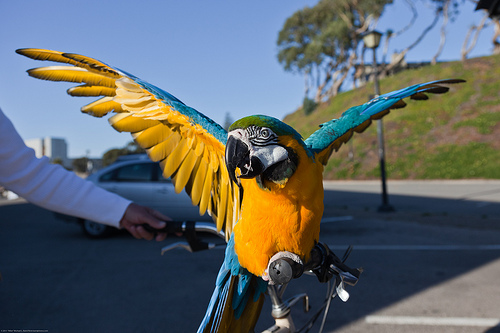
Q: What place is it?
A: It is a parking lot.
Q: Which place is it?
A: It is a parking lot.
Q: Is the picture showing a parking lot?
A: Yes, it is showing a parking lot.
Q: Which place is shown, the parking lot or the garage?
A: It is the parking lot.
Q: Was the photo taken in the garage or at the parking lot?
A: It was taken at the parking lot.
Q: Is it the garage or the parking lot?
A: It is the parking lot.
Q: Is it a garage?
A: No, it is a parking lot.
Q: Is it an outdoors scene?
A: Yes, it is outdoors.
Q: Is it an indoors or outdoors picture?
A: It is outdoors.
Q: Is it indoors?
A: No, it is outdoors.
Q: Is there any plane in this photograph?
A: No, there are no airplanes.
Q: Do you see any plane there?
A: No, there are no airplanes.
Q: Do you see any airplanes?
A: No, there are no airplanes.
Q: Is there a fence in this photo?
A: No, there are no fences.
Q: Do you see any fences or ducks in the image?
A: No, there are no fences or ducks.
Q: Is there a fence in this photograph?
A: No, there are no fences.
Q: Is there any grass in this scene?
A: Yes, there is grass.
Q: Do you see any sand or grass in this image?
A: Yes, there is grass.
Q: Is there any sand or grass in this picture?
A: Yes, there is grass.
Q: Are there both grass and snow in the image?
A: No, there is grass but no snow.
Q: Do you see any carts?
A: No, there are no carts.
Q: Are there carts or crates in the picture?
A: No, there are no carts or crates.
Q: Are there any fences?
A: No, there are no fences.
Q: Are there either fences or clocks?
A: No, there are no fences or clocks.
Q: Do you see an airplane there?
A: No, there are no airplanes.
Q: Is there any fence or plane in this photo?
A: No, there are no airplanes or fences.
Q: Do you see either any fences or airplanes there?
A: No, there are no airplanes or fences.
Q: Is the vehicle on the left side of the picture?
A: Yes, the vehicle is on the left of the image.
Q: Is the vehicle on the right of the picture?
A: No, the vehicle is on the left of the image.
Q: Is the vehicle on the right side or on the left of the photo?
A: The vehicle is on the left of the image.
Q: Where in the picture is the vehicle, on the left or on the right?
A: The vehicle is on the left of the image.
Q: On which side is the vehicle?
A: The vehicle is on the left of the image.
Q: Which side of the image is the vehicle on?
A: The vehicle is on the left of the image.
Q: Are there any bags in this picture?
A: No, there are no bags.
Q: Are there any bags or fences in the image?
A: No, there are no bags or fences.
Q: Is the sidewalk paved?
A: Yes, the sidewalk is paved.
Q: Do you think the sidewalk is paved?
A: Yes, the sidewalk is paved.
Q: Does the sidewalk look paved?
A: Yes, the sidewalk is paved.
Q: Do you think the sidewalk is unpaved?
A: No, the sidewalk is paved.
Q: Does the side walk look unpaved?
A: No, the side walk is paved.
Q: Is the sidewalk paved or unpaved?
A: The sidewalk is paved.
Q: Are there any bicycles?
A: Yes, there is a bicycle.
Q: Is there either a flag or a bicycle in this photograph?
A: Yes, there is a bicycle.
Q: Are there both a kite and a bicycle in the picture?
A: No, there is a bicycle but no kites.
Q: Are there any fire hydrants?
A: No, there are no fire hydrants.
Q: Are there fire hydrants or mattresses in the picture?
A: No, there are no fire hydrants or mattresses.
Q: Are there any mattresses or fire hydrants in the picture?
A: No, there are no fire hydrants or mattresses.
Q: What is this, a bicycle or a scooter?
A: This is a bicycle.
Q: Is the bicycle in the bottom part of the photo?
A: Yes, the bicycle is in the bottom of the image.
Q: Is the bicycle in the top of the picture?
A: No, the bicycle is in the bottom of the image.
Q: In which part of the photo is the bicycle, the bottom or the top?
A: The bicycle is in the bottom of the image.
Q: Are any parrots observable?
A: Yes, there is a parrot.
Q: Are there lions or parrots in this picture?
A: Yes, there is a parrot.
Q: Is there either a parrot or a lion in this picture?
A: Yes, there is a parrot.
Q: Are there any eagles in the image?
A: No, there are no eagles.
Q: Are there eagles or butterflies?
A: No, there are no eagles or butterflies.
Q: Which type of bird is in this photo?
A: The bird is a parrot.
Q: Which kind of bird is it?
A: The bird is a parrot.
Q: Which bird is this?
A: This is a parrot.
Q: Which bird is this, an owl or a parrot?
A: This is a parrot.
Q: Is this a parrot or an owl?
A: This is a parrot.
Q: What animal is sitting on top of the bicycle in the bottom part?
A: The parrot is sitting on top of the bicycle.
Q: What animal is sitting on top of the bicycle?
A: The parrot is sitting on top of the bicycle.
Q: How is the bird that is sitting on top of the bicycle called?
A: The bird is a parrot.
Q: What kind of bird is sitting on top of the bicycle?
A: The bird is a parrot.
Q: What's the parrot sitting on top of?
A: The parrot is sitting on top of the bicycle.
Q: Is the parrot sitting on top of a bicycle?
A: Yes, the parrot is sitting on top of a bicycle.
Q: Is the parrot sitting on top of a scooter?
A: No, the parrot is sitting on top of a bicycle.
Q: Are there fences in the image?
A: No, there are no fences.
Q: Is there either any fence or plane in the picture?
A: No, there are no fences or airplanes.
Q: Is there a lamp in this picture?
A: Yes, there is a lamp.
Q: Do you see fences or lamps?
A: Yes, there is a lamp.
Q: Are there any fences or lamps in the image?
A: Yes, there is a lamp.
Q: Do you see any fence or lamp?
A: Yes, there is a lamp.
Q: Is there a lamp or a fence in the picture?
A: Yes, there is a lamp.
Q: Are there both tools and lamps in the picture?
A: No, there is a lamp but no tools.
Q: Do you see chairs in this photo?
A: No, there are no chairs.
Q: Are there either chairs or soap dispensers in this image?
A: No, there are no chairs or soap dispensers.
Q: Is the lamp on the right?
A: Yes, the lamp is on the right of the image.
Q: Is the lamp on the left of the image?
A: No, the lamp is on the right of the image.